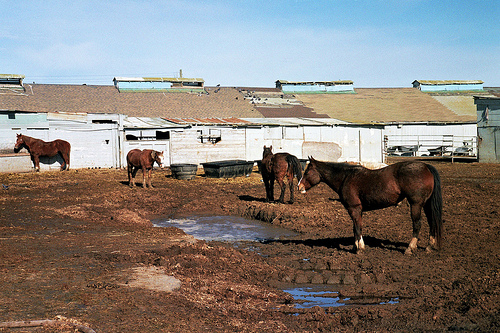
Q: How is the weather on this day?
A: It is clear.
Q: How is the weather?
A: It is clear.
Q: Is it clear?
A: Yes, it is clear.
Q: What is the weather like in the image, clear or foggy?
A: It is clear.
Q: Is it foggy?
A: No, it is clear.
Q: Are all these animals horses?
A: Yes, all the animals are horses.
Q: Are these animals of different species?
A: No, all the animals are horses.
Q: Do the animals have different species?
A: No, all the animals are horses.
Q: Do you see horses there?
A: Yes, there are horses.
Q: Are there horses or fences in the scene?
A: Yes, there are horses.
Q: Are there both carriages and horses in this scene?
A: No, there are horses but no carriages.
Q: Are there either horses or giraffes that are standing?
A: Yes, the horses are standing.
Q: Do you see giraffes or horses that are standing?
A: Yes, the horses are standing.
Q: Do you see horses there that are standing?
A: Yes, there are horses that are standing.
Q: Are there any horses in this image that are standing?
A: Yes, there are horses that are standing.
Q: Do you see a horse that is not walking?
A: Yes, there are horses that are standing .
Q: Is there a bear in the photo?
A: No, there are no bears.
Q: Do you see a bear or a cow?
A: No, there are no bears or cows.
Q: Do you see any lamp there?
A: No, there are no lamps.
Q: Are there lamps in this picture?
A: No, there are no lamps.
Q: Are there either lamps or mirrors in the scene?
A: No, there are no lamps or mirrors.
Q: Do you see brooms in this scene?
A: No, there are no brooms.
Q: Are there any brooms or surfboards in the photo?
A: No, there are no brooms or surfboards.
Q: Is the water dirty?
A: Yes, the water is dirty.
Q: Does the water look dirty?
A: Yes, the water is dirty.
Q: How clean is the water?
A: The water is dirty.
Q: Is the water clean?
A: No, the water is dirty.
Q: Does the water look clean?
A: No, the water is dirty.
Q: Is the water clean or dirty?
A: The water is dirty.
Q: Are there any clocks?
A: No, there are no clocks.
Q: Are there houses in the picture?
A: No, there are no houses.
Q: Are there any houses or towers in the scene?
A: No, there are no houses or towers.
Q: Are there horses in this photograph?
A: Yes, there is a horse.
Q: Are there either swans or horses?
A: Yes, there is a horse.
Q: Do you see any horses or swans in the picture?
A: Yes, there is a horse.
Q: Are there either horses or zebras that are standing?
A: Yes, the horse is standing.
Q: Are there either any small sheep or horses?
A: Yes, there is a small horse.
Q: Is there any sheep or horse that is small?
A: Yes, the horse is small.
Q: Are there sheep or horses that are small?
A: Yes, the horse is small.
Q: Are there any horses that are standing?
A: Yes, there is a horse that is standing.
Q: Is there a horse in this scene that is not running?
A: Yes, there is a horse that is standing.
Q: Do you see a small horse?
A: Yes, there is a small horse.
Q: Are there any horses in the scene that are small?
A: Yes, there is a horse that is small.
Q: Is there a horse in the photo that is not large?
A: Yes, there is a small horse.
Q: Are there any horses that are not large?
A: Yes, there is a small horse.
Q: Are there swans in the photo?
A: No, there are no swans.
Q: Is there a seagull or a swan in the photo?
A: No, there are no swans or seagulls.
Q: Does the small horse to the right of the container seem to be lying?
A: No, the horse is standing.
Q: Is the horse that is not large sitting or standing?
A: The horse is standing.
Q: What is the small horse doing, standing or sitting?
A: The horse is standing.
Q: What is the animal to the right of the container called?
A: The animal is a horse.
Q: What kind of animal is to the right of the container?
A: The animal is a horse.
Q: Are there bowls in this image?
A: No, there are no bowls.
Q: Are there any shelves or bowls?
A: No, there are no bowls or shelves.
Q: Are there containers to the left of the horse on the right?
A: Yes, there is a container to the left of the horse.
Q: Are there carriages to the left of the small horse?
A: No, there is a container to the left of the horse.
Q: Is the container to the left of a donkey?
A: No, the container is to the left of a horse.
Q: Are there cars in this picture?
A: No, there are no cars.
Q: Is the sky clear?
A: Yes, the sky is clear.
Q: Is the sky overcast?
A: No, the sky is clear.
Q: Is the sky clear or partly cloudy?
A: The sky is clear.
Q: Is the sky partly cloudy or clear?
A: The sky is clear.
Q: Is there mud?
A: Yes, there is mud.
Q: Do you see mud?
A: Yes, there is mud.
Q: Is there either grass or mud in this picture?
A: Yes, there is mud.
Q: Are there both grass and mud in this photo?
A: No, there is mud but no grass.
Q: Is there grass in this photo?
A: No, there is no grass.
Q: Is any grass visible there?
A: No, there is no grass.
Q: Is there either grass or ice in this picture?
A: No, there are no grass or ice.